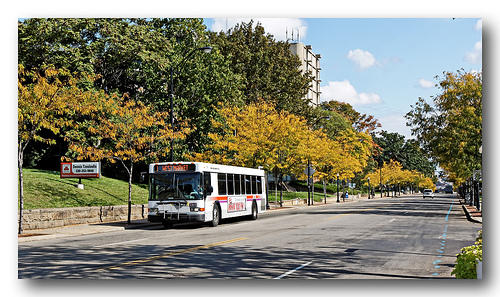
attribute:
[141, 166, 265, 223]
bus — white, parked, driving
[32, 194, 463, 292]
road — gray, asphalt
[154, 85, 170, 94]
leaves — green, different colors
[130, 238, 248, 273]
lines — yellow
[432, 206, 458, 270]
lines — blue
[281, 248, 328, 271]
lines — white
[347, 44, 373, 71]
cloud — white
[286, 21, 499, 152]
sky — blue, cloudy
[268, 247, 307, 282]
stripe — white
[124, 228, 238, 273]
stripe — yellow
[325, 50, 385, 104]
clouds — few, white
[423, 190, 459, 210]
cars — heading away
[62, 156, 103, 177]
sign — state farm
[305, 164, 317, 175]
sign — stop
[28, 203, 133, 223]
wall — stone, small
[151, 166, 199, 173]
board — digital